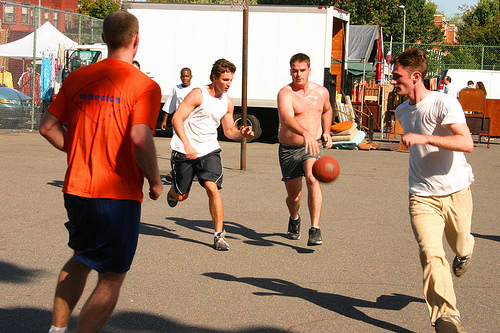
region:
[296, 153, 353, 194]
the ball is in the air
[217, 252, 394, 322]
shadow is on th ground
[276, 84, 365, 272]
the man is shirtless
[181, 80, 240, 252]
the man is wearing a vest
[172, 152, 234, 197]
the shorts are black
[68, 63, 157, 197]
the shirt is orange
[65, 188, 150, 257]
the short is blue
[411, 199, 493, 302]
the pants are brown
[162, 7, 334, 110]
the lorry is white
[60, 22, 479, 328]
five people are in the court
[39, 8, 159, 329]
a man wearing an orange shirt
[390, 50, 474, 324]
a man in tan pants and a white shirt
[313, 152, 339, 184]
an orange basket ball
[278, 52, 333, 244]
a man wearing shorts and no shirt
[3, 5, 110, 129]
tall chain link fence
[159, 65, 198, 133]
dark skinned man in a white shirt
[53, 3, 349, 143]
white box truck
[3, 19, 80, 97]
a white tent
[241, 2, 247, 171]
wooden utility pole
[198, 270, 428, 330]
shadow of a man on the ground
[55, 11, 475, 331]
man playing basketball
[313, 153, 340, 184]
a brown ball above the ground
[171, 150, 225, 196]
man wearing black shorts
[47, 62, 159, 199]
man wearing an range shirt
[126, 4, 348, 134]
a black van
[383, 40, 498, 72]
a green metal fence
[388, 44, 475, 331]
a man running on a concrete floor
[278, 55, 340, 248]
man dribbling a basketball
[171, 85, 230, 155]
man wearing a white tank top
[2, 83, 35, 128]
front of a parked blue car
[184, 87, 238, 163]
the vest is white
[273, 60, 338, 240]
the guy is sweating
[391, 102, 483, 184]
the tshirt is white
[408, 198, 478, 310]
the pants are brwon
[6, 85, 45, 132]
the car is grey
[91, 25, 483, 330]
five peole are in the court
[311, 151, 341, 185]
a brown basketball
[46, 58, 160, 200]
a orange t shirt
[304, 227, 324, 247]
a black and white tennis shoe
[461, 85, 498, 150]
brown furniture in the back ground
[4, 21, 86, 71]
a white tent in front of a truck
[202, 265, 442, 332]
a shadow of a man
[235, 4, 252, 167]
a rusty metal pole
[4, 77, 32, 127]
the front end of a car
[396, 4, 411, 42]
a gray metal light pole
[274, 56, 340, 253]
a man bouncing a ball